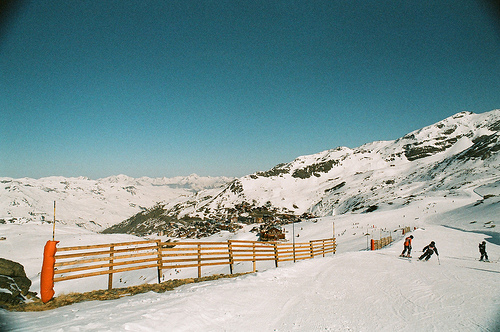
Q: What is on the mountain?
A: Snow.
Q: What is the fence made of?
A: Wood.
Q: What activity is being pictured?
A: Skiing.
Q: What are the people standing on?
A: Snow.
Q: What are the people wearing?
A: Snow coats.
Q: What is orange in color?
A: The Fence.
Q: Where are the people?
A: On mountain.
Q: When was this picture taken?
A: During the winter.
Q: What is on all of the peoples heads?
A: Hats.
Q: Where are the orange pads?
A: On fence.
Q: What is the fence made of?
A: Wood.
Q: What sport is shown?
A: Skiing.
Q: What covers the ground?
A: Snow.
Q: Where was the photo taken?
A: Mountains.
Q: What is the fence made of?
A: Wood.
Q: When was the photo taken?
A: Winter.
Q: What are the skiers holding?
A: Poles.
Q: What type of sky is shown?
A: Clear.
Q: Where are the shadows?
A: Each corner.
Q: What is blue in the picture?
A: Sky.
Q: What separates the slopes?
A: Orange fence.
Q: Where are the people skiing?
A: On the snow.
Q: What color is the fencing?
A: Orange.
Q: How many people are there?
A: Three.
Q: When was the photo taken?
A: Daytime.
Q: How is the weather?
A: Clear and sunny.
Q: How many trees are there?
A: None.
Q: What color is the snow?
A: White.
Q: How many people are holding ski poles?
A: One.